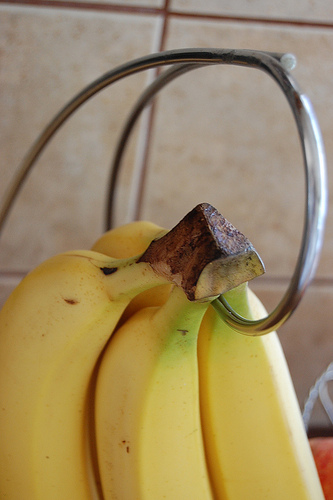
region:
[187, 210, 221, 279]
stem of the banana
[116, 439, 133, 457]
marking on the banana peel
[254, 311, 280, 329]
a metal ring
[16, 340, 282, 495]
the bananas are yellow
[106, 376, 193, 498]
the peel is yellow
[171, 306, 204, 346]
tip of the banana is green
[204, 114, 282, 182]
the tile is brown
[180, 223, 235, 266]
the stem of the bananas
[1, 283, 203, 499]
two bananas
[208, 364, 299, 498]
a yellow banana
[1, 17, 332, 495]
the bananas are hanging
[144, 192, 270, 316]
the stem of the bananas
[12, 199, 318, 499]
the bananas are yellow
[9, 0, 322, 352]
wall behind the bananas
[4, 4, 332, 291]
the wall is tiled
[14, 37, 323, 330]
the metal device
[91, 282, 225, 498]
the banana is hanging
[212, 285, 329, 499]
the banana is hanging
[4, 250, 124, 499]
the banana is hanging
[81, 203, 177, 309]
the banana is hanging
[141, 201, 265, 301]
the brown end of a banana.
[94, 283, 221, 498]
a yellow and green banana.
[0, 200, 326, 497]
a bunch of bananas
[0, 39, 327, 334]
a large metal banana hook.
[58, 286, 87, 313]
a brown spot on a banana.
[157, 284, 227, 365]
a green spot on a yellow banana.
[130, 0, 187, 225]
a line on a wall.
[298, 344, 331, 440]
a white object in a kitchen.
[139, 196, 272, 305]
the tip of a bunch of bananas.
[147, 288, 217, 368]
a green pot on a banana.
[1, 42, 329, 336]
a silver hook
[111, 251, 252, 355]
a green spot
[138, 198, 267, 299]
the stem of fruit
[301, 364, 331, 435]
a wire basket on right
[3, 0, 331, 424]
a concrete wall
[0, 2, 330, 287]
lines on wall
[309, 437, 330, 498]
a red object on right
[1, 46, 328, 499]
a display of fruit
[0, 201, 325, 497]
hanging fruit from stand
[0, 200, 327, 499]
A bunch of yellow bananas.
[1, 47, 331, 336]
A metal banana hanger.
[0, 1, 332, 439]
Tan tiled background wall.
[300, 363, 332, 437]
A silver colored handle.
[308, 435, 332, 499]
A orange colored item.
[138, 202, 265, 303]
Brown banana bunch stem.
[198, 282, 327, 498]
A yellow colored banana.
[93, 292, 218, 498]
A ripe yellow banana.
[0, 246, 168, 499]
Ready to eat banana.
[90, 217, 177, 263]
Part of a banana.